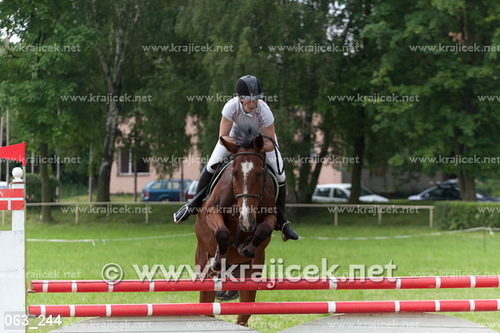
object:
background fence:
[26, 201, 437, 228]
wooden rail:
[27, 201, 438, 227]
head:
[236, 75, 264, 113]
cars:
[140, 178, 492, 203]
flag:
[0, 141, 28, 210]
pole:
[22, 142, 27, 198]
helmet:
[236, 75, 264, 101]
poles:
[148, 277, 300, 316]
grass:
[97, 242, 136, 252]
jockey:
[174, 75, 299, 243]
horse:
[195, 118, 278, 327]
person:
[173, 75, 300, 241]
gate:
[25, 275, 500, 319]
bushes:
[432, 200, 499, 233]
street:
[140, 182, 500, 212]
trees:
[0, 1, 497, 224]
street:
[0, 191, 500, 220]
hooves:
[209, 241, 257, 273]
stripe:
[241, 160, 254, 226]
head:
[219, 133, 268, 232]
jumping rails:
[28, 275, 499, 318]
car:
[139, 178, 191, 202]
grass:
[318, 219, 481, 262]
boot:
[276, 182, 295, 242]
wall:
[0, 282, 499, 332]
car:
[407, 178, 500, 202]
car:
[313, 183, 391, 203]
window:
[115, 145, 153, 178]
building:
[109, 109, 445, 195]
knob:
[11, 166, 25, 183]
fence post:
[0, 166, 28, 332]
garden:
[414, 200, 470, 246]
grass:
[376, 233, 469, 280]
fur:
[239, 159, 254, 227]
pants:
[197, 135, 287, 208]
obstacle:
[30, 275, 499, 318]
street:
[106, 186, 198, 211]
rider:
[175, 75, 300, 240]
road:
[30, 193, 500, 210]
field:
[31, 184, 446, 221]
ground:
[0, 193, 500, 333]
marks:
[28, 276, 500, 318]